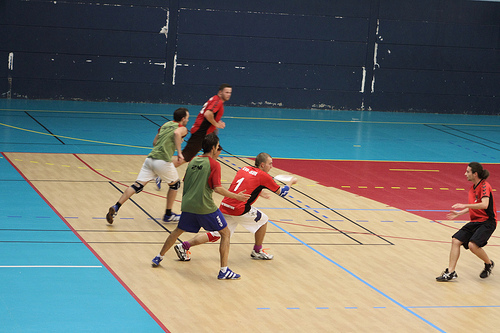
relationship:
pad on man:
[169, 179, 182, 190] [105, 109, 190, 224]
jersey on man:
[219, 165, 280, 214] [218, 153, 299, 262]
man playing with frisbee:
[218, 153, 299, 262] [273, 172, 297, 185]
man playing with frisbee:
[152, 133, 252, 281] [273, 172, 297, 185]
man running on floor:
[218, 153, 299, 262] [2, 99, 497, 331]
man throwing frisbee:
[218, 153, 299, 262] [273, 172, 297, 185]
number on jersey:
[234, 175, 245, 191] [219, 165, 280, 214]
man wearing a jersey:
[218, 153, 299, 262] [219, 165, 280, 214]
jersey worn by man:
[190, 91, 224, 135] [173, 82, 234, 169]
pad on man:
[132, 178, 145, 194] [105, 109, 190, 224]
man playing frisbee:
[218, 153, 299, 262] [273, 172, 297, 185]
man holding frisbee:
[218, 153, 299, 262] [273, 172, 297, 185]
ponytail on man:
[480, 169, 490, 181] [434, 163, 497, 284]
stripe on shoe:
[223, 269, 232, 281] [218, 267, 242, 281]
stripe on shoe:
[227, 273, 233, 278] [218, 267, 242, 281]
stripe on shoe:
[230, 272, 238, 280] [218, 267, 242, 281]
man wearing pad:
[223, 153, 289, 273] [279, 186, 290, 199]